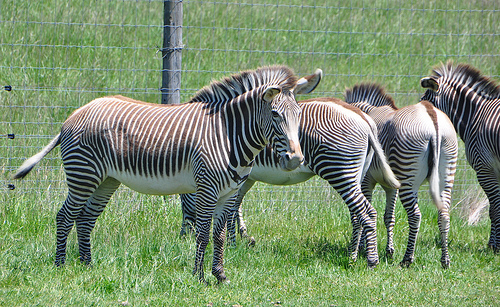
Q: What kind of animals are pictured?
A: Zebras.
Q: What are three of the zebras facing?
A: The fence.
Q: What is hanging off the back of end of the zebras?
A: Tails.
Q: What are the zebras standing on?
A: Grass.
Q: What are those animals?
A: Zebras.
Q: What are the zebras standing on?
A: The grass.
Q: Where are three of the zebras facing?
A: The fence.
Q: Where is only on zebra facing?
A: The camera.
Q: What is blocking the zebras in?
A: A fence.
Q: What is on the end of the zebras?
A: The tail.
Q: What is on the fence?
A: A piece of wood.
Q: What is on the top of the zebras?
A: The hair.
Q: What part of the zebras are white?
A: The tummy area.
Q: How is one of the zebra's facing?
A: Opposite of the others.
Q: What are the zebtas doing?
A: Standing.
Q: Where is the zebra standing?
A: A field.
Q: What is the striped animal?
A: Zebra.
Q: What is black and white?
A: Zebra.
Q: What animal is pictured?
A: Zebra.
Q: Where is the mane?
A: On zebra.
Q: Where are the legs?
A: On zebra.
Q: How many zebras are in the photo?
A: Four.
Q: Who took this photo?
A: A photographer.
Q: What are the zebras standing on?
A: Grass.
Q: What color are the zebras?
A: Black, white and brown.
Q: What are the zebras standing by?
A: A fence.